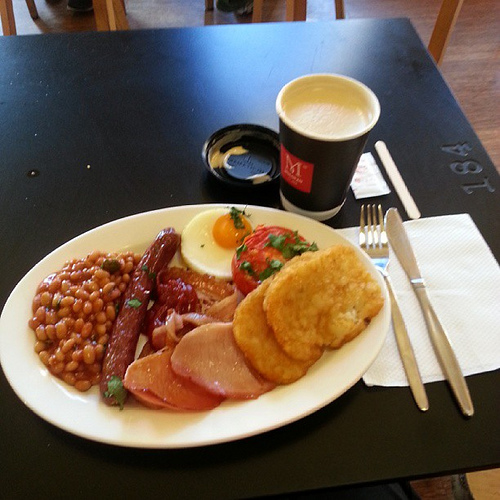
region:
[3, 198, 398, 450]
the white plate on the table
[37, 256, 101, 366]
the piles of beans on the plate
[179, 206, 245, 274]
the egg on the plate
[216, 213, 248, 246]
the yellow yolk on the egg white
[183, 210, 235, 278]
the egg whites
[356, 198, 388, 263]
the prongs on the fork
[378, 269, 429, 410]
the handle of the fork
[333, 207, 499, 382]
the white napkin on the table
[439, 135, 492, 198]
the numbers 184 on the table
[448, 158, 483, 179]
the 8 on the table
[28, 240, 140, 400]
Brown beans on a plate.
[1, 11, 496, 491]
A black table top.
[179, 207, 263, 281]
A cooked egg with the yolk unbroken.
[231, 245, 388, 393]
Rectangular golden hash browns.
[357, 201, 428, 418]
A silver fork.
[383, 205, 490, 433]
A silver butter knife.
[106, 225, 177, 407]
A long dark colored sausage.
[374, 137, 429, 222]
A small wooden stirring stick.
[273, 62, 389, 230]
A coffee cup with liquid in it.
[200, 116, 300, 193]
A black lid for a cup.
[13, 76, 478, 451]
breakfast on a table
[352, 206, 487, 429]
utensils on a white napkin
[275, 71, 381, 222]
a cup of coffee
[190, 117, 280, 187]
a black lid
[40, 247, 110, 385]
beans on a plate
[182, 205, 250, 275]
a sunny side up egg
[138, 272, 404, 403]
hash browns and ham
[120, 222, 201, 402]
sausage and bacon on a plate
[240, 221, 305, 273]
a slice of tomato with parsley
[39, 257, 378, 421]
a plate with sausage, ham, egg and beans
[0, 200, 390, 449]
the white plate with food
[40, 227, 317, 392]
the food on the plate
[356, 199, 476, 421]
the utensils next to the plate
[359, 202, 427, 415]
the fork next to the plate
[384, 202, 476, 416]
the butterknife next to the fork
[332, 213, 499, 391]
the white napkin under the utensils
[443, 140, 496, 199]
the number 184 on the table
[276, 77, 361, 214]
the black cup on the table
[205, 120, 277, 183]
the black cover to the cup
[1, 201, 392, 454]
The plate is white.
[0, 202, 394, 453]
The plate is oval.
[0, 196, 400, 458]
The plate is full.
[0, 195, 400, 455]
The plate is in use.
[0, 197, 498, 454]
Knife and fork beside a plate.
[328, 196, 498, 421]
Knife and fork on a napkin.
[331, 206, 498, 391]
The napkin is white.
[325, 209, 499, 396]
The napkin is paper.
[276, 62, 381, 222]
The cup is full.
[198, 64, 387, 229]
The lid is beside the cup.